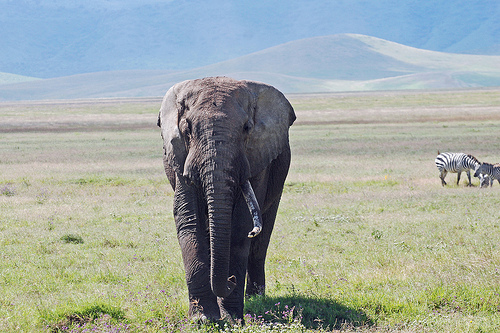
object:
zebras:
[435, 151, 489, 188]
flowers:
[275, 303, 282, 315]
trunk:
[200, 174, 239, 297]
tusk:
[239, 177, 264, 238]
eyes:
[243, 121, 250, 134]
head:
[156, 75, 295, 296]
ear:
[240, 79, 296, 177]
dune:
[0, 33, 499, 102]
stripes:
[437, 154, 448, 170]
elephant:
[157, 76, 296, 329]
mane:
[467, 154, 481, 166]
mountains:
[0, 0, 499, 80]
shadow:
[243, 295, 378, 329]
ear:
[157, 77, 191, 176]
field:
[0, 89, 499, 332]